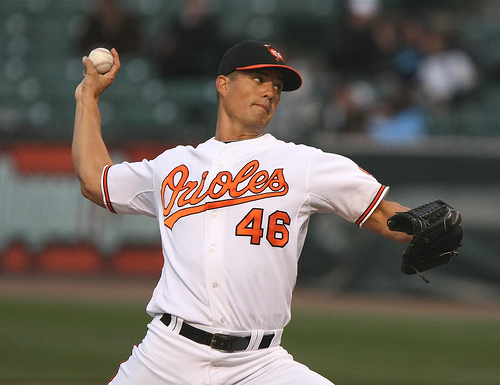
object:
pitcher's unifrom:
[101, 131, 393, 382]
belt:
[160, 313, 275, 353]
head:
[214, 40, 282, 134]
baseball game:
[6, 5, 498, 385]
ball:
[88, 47, 113, 75]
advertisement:
[1, 142, 178, 276]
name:
[159, 160, 291, 249]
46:
[235, 208, 291, 248]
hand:
[403, 212, 462, 269]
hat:
[215, 39, 300, 92]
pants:
[105, 315, 337, 384]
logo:
[159, 158, 289, 230]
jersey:
[101, 132, 389, 332]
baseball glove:
[386, 198, 464, 282]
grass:
[2, 299, 498, 381]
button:
[213, 282, 219, 288]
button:
[220, 317, 225, 322]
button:
[210, 245, 216, 252]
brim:
[239, 60, 306, 90]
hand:
[74, 47, 121, 99]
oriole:
[264, 44, 285, 61]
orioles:
[160, 160, 288, 231]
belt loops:
[168, 315, 188, 333]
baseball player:
[72, 40, 464, 385]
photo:
[1, 4, 500, 381]